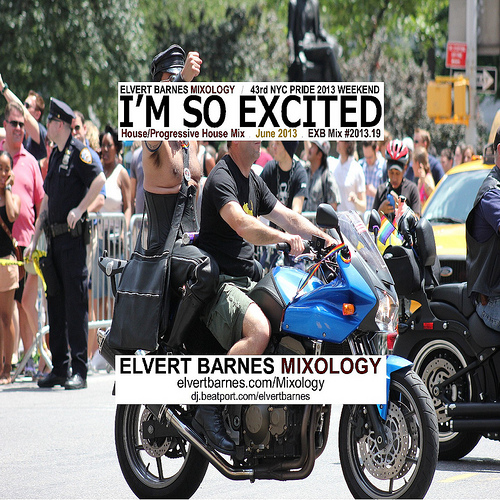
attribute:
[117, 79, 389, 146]
sign — white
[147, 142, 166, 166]
armpit — hairy, dark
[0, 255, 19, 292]
skirt — pink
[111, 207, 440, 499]
bike — blue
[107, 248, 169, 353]
bag — black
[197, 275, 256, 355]
shorts — green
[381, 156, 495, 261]
vehicle — yellow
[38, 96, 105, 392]
officer — police, standing, back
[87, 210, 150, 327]
fence — metal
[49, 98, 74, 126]
hat — dark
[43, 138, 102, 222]
shirt — dark, black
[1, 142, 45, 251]
shirt — pink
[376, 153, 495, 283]
taxi — yellow, middle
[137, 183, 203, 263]
corset — black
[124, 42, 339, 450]
people — riding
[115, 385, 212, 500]
tire — black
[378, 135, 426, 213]
man — riding, shirtless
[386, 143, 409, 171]
helmet — red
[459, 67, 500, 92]
arrow — pointing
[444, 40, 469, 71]
sign — red, attached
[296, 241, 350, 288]
flag — rainbow